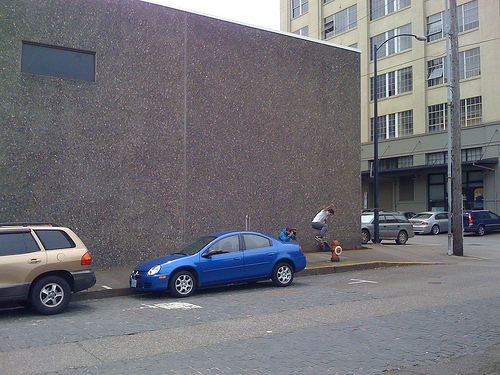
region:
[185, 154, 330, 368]
the car is blue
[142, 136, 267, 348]
the car is blue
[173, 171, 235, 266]
the car is blue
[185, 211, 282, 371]
the car is blue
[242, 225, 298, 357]
the car is blue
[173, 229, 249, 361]
the car is blue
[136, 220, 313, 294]
There is a blue car parked.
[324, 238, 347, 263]
The fire hydrant is orange.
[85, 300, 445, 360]
The asphalt is dry.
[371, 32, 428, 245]
This is a light pole.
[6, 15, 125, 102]
There is a window on the side of building.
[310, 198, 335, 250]
The person is jumping in the air.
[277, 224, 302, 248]
This person is taking a photograph.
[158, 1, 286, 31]
The sky is cloudy.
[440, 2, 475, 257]
This is a telephone pole.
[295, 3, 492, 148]
This building has many windows.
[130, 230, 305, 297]
a parked blue car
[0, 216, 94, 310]
a parked gold SUV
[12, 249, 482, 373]
a brick paved city street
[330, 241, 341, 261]
a red and white fire hydrant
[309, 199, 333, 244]
a skateboarder in air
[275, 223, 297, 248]
a crouching photographer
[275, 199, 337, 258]
person taking photographs of skateboarder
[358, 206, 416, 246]
a parked lime green car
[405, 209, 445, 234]
a parked silver car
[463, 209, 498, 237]
a parked blue car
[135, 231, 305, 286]
A blue car is parked on the side of the road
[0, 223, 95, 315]
A tan car is parked in front of the blue car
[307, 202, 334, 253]
The man is skateboarding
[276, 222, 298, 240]
A man is filming the skateboarder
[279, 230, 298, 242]
The cameraman is wearing blue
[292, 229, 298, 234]
The man is holding a camera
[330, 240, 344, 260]
A fire hydrant is in front of the skateboarder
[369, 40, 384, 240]
A lamppost is on the corner of the sidewalk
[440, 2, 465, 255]
A telephone pole is by the street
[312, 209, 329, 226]
The skateboarder is wearing white